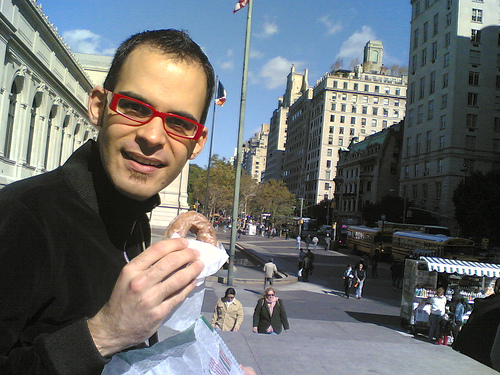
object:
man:
[1, 28, 215, 374]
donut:
[165, 210, 217, 244]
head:
[87, 27, 216, 198]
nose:
[138, 114, 167, 146]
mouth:
[118, 146, 169, 174]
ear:
[85, 86, 107, 129]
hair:
[101, 28, 216, 127]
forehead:
[116, 45, 208, 123]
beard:
[129, 171, 151, 183]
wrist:
[78, 313, 121, 356]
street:
[203, 217, 500, 374]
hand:
[107, 235, 204, 345]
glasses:
[103, 89, 206, 143]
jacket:
[2, 139, 161, 374]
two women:
[210, 286, 291, 335]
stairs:
[220, 332, 500, 374]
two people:
[422, 286, 460, 341]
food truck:
[398, 255, 500, 330]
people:
[355, 263, 369, 298]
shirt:
[263, 296, 278, 331]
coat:
[209, 299, 244, 330]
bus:
[344, 226, 390, 258]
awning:
[418, 254, 499, 280]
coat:
[455, 305, 466, 322]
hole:
[187, 223, 203, 240]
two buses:
[344, 224, 482, 268]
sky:
[36, 0, 411, 170]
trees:
[242, 176, 296, 239]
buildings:
[397, 0, 499, 238]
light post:
[401, 197, 409, 226]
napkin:
[159, 232, 231, 332]